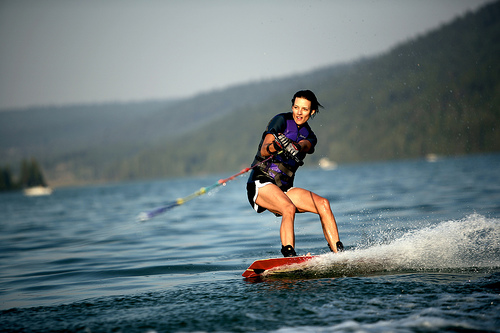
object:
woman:
[244, 88, 345, 258]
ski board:
[241, 253, 384, 281]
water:
[305, 208, 500, 279]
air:
[0, 0, 500, 185]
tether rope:
[139, 126, 307, 224]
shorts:
[245, 178, 295, 217]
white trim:
[253, 179, 274, 213]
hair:
[290, 88, 325, 119]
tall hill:
[0, 0, 500, 188]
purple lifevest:
[250, 111, 319, 187]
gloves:
[271, 132, 291, 151]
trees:
[27, 155, 49, 188]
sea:
[0, 152, 500, 332]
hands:
[272, 132, 291, 151]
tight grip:
[268, 127, 305, 166]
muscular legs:
[245, 174, 298, 258]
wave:
[332, 270, 500, 293]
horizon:
[45, 150, 500, 188]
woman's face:
[291, 97, 311, 125]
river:
[0, 151, 499, 332]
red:
[241, 254, 323, 279]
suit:
[245, 111, 318, 217]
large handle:
[269, 127, 305, 166]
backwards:
[237, 88, 346, 284]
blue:
[13, 173, 230, 312]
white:
[421, 234, 458, 258]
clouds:
[33, 3, 40, 10]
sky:
[0, 0, 500, 114]